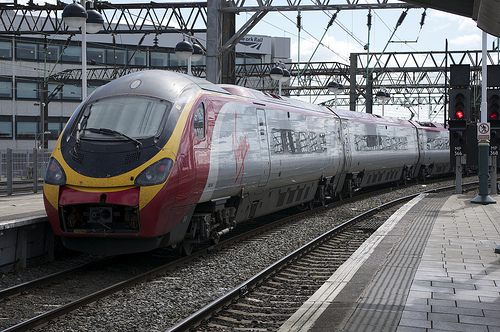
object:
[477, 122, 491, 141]
no walking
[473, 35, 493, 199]
post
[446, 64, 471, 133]
ligh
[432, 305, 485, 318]
bricks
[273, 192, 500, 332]
sidewalk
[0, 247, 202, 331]
train rail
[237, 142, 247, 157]
red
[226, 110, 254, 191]
sign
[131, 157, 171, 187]
headlight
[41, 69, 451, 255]
large train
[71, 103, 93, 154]
wiper blade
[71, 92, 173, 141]
windshield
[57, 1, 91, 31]
lights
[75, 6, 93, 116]
light post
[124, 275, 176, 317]
gravel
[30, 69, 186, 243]
front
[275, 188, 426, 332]
curb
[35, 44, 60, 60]
windows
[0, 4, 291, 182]
building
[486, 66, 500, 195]
"a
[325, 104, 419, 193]
car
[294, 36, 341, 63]
clouds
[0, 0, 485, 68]
sky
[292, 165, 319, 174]
silver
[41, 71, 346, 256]
engine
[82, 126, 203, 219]
red yellow and black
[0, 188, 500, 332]
platform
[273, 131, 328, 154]
long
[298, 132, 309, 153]
window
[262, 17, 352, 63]
overhead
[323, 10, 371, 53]
lines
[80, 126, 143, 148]
wiper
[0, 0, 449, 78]
distance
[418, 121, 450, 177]
back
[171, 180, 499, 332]
track